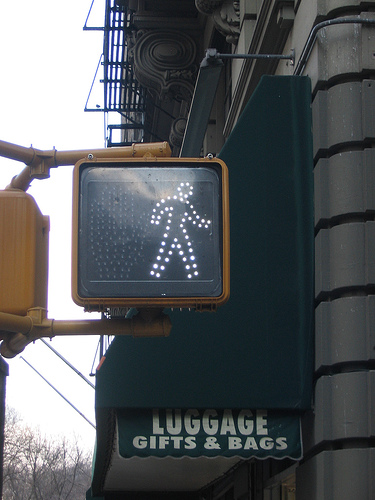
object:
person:
[146, 178, 214, 287]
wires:
[20, 354, 95, 431]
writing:
[150, 411, 270, 437]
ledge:
[85, 0, 165, 110]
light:
[177, 55, 228, 162]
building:
[84, 0, 374, 499]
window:
[281, 471, 298, 499]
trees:
[0, 410, 83, 497]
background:
[0, 0, 374, 499]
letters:
[157, 434, 170, 451]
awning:
[82, 74, 313, 499]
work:
[194, 1, 241, 44]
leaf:
[230, 1, 239, 14]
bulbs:
[145, 181, 218, 280]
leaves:
[9, 414, 84, 488]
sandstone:
[127, 27, 198, 159]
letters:
[226, 434, 243, 452]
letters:
[147, 432, 158, 451]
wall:
[312, 0, 374, 498]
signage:
[70, 155, 232, 308]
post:
[0, 139, 37, 170]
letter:
[149, 409, 163, 434]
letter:
[163, 411, 183, 435]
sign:
[117, 409, 303, 461]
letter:
[183, 407, 202, 436]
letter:
[201, 407, 219, 437]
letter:
[216, 406, 239, 435]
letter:
[236, 406, 256, 437]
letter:
[253, 406, 271, 436]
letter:
[226, 436, 243, 451]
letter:
[239, 433, 259, 450]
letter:
[258, 436, 274, 451]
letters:
[132, 436, 148, 451]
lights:
[78, 165, 223, 301]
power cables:
[38, 336, 96, 390]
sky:
[0, 0, 123, 500]